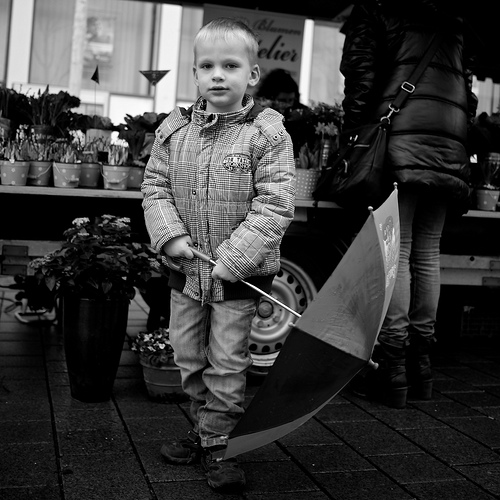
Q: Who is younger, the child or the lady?
A: The child is younger than the lady.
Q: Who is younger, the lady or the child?
A: The child is younger than the lady.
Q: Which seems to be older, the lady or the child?
A: The lady is older than the child.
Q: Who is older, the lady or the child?
A: The lady is older than the child.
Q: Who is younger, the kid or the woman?
A: The kid is younger than the woman.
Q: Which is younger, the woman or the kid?
A: The kid is younger than the woman.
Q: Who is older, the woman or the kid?
A: The woman is older than the kid.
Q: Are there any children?
A: Yes, there is a child.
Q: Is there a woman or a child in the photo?
A: Yes, there is a child.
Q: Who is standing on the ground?
A: The child is standing on the ground.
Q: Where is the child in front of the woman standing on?
A: The child is standing on the ground.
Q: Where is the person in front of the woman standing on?
A: The child is standing on the ground.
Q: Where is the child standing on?
A: The child is standing on the ground.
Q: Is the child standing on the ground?
A: Yes, the child is standing on the ground.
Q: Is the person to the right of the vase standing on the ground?
A: Yes, the child is standing on the ground.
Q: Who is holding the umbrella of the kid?
A: The kid is holding the umbrella.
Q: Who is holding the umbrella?
A: The kid is holding the umbrella.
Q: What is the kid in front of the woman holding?
A: The kid is holding the umbrella.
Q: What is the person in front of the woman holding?
A: The kid is holding the umbrella.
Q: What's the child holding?
A: The kid is holding the umbrella.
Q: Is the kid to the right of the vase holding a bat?
A: No, the child is holding the umbrella.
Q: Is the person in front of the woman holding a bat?
A: No, the child is holding the umbrella.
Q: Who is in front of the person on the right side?
A: The child is in front of the woman.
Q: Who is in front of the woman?
A: The child is in front of the woman.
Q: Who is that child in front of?
A: The child is in front of the woman.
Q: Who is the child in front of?
A: The child is in front of the woman.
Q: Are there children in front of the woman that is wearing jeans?
A: Yes, there is a child in front of the woman.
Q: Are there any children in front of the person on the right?
A: Yes, there is a child in front of the woman.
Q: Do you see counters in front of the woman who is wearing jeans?
A: No, there is a child in front of the woman.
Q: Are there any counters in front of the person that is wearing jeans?
A: No, there is a child in front of the woman.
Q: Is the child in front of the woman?
A: Yes, the child is in front of the woman.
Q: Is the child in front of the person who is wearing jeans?
A: Yes, the child is in front of the woman.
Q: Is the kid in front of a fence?
A: No, the kid is in front of the woman.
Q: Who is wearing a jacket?
A: The child is wearing a jacket.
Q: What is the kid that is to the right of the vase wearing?
A: The child is wearing a jacket.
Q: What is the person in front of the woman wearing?
A: The child is wearing a jacket.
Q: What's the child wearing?
A: The child is wearing a jacket.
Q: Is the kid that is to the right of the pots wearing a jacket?
A: Yes, the child is wearing a jacket.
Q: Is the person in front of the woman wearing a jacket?
A: Yes, the child is wearing a jacket.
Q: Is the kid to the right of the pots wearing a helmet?
A: No, the child is wearing a jacket.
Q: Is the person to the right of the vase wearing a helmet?
A: No, the child is wearing a jacket.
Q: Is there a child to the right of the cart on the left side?
A: Yes, there is a child to the right of the cart.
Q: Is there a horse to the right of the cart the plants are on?
A: No, there is a child to the right of the cart.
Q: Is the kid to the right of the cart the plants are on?
A: Yes, the kid is to the right of the cart.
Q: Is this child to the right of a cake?
A: No, the child is to the right of the cart.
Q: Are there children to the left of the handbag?
A: Yes, there is a child to the left of the handbag.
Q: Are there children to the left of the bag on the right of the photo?
A: Yes, there is a child to the left of the handbag.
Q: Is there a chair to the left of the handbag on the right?
A: No, there is a child to the left of the handbag.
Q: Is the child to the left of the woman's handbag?
A: Yes, the child is to the left of the handbag.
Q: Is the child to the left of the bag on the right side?
A: Yes, the child is to the left of the handbag.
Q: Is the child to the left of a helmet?
A: No, the child is to the left of the handbag.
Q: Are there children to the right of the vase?
A: Yes, there is a child to the right of the vase.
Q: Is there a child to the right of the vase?
A: Yes, there is a child to the right of the vase.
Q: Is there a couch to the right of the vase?
A: No, there is a child to the right of the vase.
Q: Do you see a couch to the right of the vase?
A: No, there is a child to the right of the vase.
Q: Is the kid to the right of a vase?
A: Yes, the kid is to the right of a vase.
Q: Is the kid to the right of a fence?
A: No, the kid is to the right of a vase.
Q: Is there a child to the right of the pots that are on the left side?
A: Yes, there is a child to the right of the pots.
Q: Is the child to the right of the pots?
A: Yes, the child is to the right of the pots.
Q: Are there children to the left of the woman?
A: Yes, there is a child to the left of the woman.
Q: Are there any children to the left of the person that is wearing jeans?
A: Yes, there is a child to the left of the woman.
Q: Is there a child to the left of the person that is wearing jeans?
A: Yes, there is a child to the left of the woman.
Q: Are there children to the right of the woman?
A: No, the child is to the left of the woman.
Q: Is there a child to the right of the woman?
A: No, the child is to the left of the woman.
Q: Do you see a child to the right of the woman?
A: No, the child is to the left of the woman.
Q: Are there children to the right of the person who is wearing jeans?
A: No, the child is to the left of the woman.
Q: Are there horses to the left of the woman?
A: No, there is a child to the left of the woman.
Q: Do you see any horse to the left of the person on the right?
A: No, there is a child to the left of the woman.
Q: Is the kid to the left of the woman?
A: Yes, the kid is to the left of the woman.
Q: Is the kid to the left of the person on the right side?
A: Yes, the kid is to the left of the woman.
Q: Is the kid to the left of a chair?
A: No, the kid is to the left of the woman.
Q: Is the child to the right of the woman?
A: No, the child is to the left of the woman.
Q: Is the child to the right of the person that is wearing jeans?
A: No, the child is to the left of the woman.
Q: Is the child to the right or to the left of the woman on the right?
A: The child is to the left of the woman.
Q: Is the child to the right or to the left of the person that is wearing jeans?
A: The child is to the left of the woman.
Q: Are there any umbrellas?
A: Yes, there is an umbrella.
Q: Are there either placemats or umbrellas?
A: Yes, there is an umbrella.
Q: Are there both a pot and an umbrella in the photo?
A: Yes, there are both an umbrella and a pot.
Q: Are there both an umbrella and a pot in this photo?
A: Yes, there are both an umbrella and a pot.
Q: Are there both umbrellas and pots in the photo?
A: Yes, there are both an umbrella and a pot.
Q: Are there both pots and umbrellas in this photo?
A: Yes, there are both an umbrella and a pot.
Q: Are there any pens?
A: No, there are no pens.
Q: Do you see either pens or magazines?
A: No, there are no pens or magazines.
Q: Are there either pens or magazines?
A: No, there are no pens or magazines.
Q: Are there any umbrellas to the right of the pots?
A: Yes, there is an umbrella to the right of the pots.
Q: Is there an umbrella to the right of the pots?
A: Yes, there is an umbrella to the right of the pots.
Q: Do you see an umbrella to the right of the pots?
A: Yes, there is an umbrella to the right of the pots.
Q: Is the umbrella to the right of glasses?
A: No, the umbrella is to the right of the pots.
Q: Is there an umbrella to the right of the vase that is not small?
A: Yes, there is an umbrella to the right of the vase.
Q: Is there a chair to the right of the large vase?
A: No, there is an umbrella to the right of the vase.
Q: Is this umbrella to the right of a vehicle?
A: No, the umbrella is to the right of the vase.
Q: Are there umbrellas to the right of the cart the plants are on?
A: Yes, there is an umbrella to the right of the cart.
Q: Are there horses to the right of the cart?
A: No, there is an umbrella to the right of the cart.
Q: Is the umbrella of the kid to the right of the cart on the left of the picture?
A: Yes, the umbrella is to the right of the cart.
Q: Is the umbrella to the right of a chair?
A: No, the umbrella is to the right of the cart.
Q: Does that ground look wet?
A: Yes, the ground is wet.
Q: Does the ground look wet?
A: Yes, the ground is wet.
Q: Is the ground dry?
A: No, the ground is wet.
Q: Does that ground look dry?
A: No, the ground is wet.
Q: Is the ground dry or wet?
A: The ground is wet.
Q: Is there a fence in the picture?
A: No, there are no fences.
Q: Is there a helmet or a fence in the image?
A: No, there are no fences or helmets.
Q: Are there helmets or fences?
A: No, there are no fences or helmets.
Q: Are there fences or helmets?
A: No, there are no fences or helmets.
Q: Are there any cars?
A: No, there are no cars.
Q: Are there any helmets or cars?
A: No, there are no cars or helmets.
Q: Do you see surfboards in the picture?
A: No, there are no surfboards.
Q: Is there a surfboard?
A: No, there are no surfboards.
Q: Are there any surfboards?
A: No, there are no surfboards.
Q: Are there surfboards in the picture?
A: No, there are no surfboards.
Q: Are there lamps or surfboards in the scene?
A: No, there are no surfboards or lamps.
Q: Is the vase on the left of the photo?
A: Yes, the vase is on the left of the image.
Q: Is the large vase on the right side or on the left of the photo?
A: The vase is on the left of the image.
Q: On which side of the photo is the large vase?
A: The vase is on the left of the image.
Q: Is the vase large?
A: Yes, the vase is large.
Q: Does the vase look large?
A: Yes, the vase is large.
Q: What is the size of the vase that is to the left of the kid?
A: The vase is large.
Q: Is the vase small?
A: No, the vase is large.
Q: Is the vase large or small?
A: The vase is large.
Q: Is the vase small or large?
A: The vase is large.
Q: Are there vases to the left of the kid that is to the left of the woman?
A: Yes, there is a vase to the left of the child.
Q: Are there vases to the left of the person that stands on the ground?
A: Yes, there is a vase to the left of the child.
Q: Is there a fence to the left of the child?
A: No, there is a vase to the left of the child.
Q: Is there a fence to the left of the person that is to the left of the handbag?
A: No, there is a vase to the left of the child.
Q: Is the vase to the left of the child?
A: Yes, the vase is to the left of the child.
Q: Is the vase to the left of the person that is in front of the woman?
A: Yes, the vase is to the left of the child.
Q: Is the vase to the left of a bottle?
A: No, the vase is to the left of the child.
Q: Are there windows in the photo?
A: Yes, there is a window.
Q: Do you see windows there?
A: Yes, there is a window.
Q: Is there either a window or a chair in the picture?
A: Yes, there is a window.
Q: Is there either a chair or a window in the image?
A: Yes, there is a window.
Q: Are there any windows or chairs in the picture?
A: Yes, there is a window.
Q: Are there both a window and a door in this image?
A: No, there is a window but no doors.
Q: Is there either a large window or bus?
A: Yes, there is a large window.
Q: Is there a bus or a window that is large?
A: Yes, the window is large.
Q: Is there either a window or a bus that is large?
A: Yes, the window is large.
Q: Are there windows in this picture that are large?
A: Yes, there is a large window.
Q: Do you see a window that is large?
A: Yes, there is a large window.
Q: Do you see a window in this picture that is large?
A: Yes, there is a window that is large.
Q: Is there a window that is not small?
A: Yes, there is a large window.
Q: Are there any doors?
A: No, there are no doors.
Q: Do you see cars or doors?
A: No, there are no doors or cars.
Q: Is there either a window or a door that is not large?
A: No, there is a window but it is large.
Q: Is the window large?
A: Yes, the window is large.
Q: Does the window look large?
A: Yes, the window is large.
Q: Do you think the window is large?
A: Yes, the window is large.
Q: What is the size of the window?
A: The window is large.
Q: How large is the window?
A: The window is large.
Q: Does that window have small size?
A: No, the window is large.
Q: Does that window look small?
A: No, the window is large.